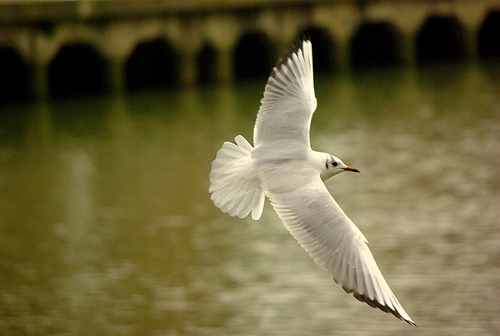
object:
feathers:
[318, 206, 414, 328]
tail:
[205, 134, 262, 221]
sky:
[0, 0, 497, 336]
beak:
[341, 166, 361, 173]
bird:
[206, 39, 418, 330]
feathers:
[205, 136, 262, 222]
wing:
[257, 168, 418, 328]